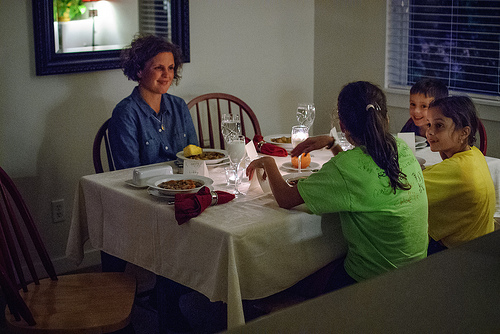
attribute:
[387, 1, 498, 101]
blind — mini, white, open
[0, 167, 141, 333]
chair — wooden, brown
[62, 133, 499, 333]
table — white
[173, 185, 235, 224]
napkin — cloth, red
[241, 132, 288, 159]
napkin — cloth, red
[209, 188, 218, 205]
ring — silver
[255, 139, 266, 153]
ring — silver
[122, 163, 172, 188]
butter dish — white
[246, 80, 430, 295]
girl — sitting, eating, young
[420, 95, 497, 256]
girl — sitting, eating, young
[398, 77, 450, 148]
boy — sitting, smiling, eating, young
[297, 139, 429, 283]
shirt — green, bright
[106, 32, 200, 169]
woman — smiling, eating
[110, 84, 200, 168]
shirt — blue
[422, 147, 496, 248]
shirt — yellow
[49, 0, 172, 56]
mirror — framed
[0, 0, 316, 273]
wall — white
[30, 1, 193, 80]
frame — black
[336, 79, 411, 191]
hair — brown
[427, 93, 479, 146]
hair — brown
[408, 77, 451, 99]
hair — brown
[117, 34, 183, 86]
hair — brown, short, curly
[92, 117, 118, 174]
chair — wooden, brown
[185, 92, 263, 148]
chair — wooden, brown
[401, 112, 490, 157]
chair — wooden, brown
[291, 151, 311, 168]
candle — orange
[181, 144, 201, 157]
cornbread — yellow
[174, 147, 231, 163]
plate — white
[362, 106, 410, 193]
ponytail — long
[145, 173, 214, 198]
plate — white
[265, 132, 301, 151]
plate — white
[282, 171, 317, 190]
plate — white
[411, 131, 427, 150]
plate — white